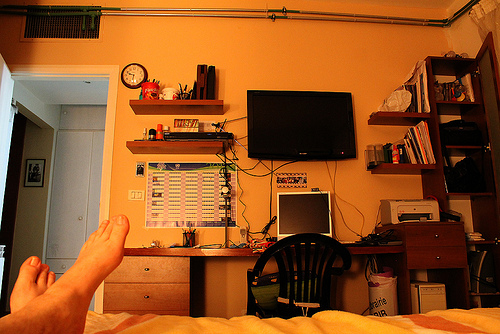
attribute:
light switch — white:
[126, 189, 145, 201]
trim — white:
[7, 63, 116, 321]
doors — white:
[44, 118, 101, 284]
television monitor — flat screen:
[248, 90, 358, 157]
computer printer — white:
[381, 197, 438, 223]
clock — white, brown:
[119, 60, 149, 90]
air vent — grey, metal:
[20, 5, 100, 37]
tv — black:
[240, 84, 367, 167]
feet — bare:
[12, 204, 135, 325]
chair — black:
[244, 218, 363, 322]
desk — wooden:
[203, 243, 252, 262]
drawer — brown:
[128, 247, 202, 322]